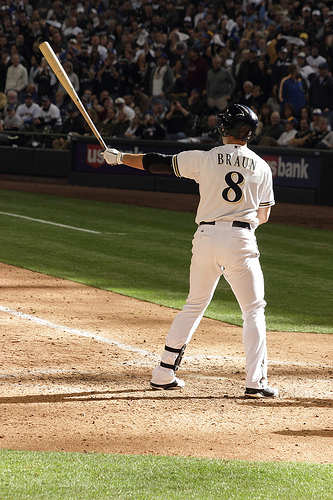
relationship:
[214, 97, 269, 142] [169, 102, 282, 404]
head of man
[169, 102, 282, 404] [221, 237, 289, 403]
man has leg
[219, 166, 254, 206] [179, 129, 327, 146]
number on shirt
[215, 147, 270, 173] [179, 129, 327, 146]
braun on shirt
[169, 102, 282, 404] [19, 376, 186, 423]
man has shadow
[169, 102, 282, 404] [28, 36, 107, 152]
man holding baseball bat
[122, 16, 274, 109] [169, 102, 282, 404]
crowd watching man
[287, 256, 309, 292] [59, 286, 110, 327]
grass touching dirt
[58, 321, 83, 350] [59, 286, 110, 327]
line on dirt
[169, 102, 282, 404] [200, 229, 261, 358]
man wearing white pants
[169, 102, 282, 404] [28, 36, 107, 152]
man with baseball bat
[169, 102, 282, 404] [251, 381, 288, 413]
man has foot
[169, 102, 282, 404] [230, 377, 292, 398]
man has shoe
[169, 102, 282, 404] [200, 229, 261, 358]
man wears white pants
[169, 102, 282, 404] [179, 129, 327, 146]
man wearing shirt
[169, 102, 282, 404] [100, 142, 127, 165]
man in glove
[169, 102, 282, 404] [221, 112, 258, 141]
man in helmet